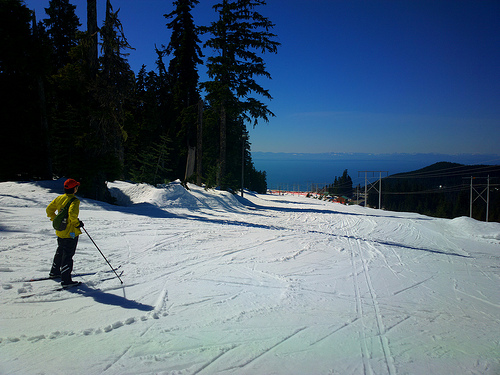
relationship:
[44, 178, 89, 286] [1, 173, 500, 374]
skier in field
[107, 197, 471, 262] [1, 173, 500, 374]
shadow on field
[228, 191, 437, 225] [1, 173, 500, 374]
shadow on field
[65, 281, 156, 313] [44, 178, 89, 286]
shadow of skier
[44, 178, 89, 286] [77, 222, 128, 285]
skier holding pole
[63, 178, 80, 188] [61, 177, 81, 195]
cap on head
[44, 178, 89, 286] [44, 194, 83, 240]
skier wearing coat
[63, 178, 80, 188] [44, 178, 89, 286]
cap on skier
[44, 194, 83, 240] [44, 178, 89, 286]
coat on skier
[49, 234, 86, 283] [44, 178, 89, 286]
pants on skier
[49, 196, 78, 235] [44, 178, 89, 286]
bag on skier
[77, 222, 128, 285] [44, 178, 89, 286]
pole held by skier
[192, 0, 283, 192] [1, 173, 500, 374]
trees lines field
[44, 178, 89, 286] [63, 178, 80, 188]
skier has cap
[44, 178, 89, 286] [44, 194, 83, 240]
skier has coat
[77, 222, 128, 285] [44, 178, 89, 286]
pole of skier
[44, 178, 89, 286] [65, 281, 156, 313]
skier casts shadow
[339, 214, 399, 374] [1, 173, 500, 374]
tracks in field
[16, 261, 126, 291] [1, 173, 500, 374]
skis in field